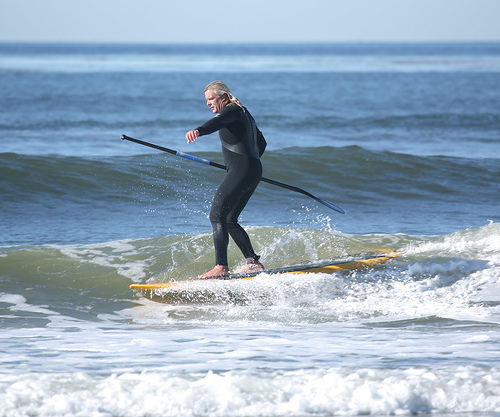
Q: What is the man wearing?
A: The man is wearing a black wetsuits.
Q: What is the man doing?
A: The man is surfing.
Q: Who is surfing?
A: A man is surfing.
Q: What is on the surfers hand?
A: The surfer is holding onto a pole.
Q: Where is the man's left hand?
A: The man's left hand is extended on the side.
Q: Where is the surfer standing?
A: The surfer is standing on a surf board.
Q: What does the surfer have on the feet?
A: The surfers feet are bare.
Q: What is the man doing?
A: Surfing.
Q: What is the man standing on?
A: Surfboard.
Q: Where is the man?
A: In the ocean.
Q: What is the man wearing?
A: Black wetsuit.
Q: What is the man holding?
A: Pole.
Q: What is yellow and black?
A: Surfboard.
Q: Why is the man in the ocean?
A: Surfing.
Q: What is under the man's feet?
A: Surfboard.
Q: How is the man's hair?
A: Long.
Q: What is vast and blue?
A: Ocean.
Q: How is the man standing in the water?
A: On a paddleboard.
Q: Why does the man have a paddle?
A: For balance and movement.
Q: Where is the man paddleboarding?
A: In the ocean.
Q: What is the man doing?
A: Surfing.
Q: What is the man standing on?
A: A surfboard.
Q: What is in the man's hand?
A: A paddle.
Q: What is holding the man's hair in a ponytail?
A: Hair tie.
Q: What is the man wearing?
A: A wet suit.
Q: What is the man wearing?
A: A wetsuit.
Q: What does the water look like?
A: Wavy.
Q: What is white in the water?
A: Foam.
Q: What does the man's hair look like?
A: Long ponytail.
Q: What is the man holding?
A: A paddle.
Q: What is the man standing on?
A: A surfboard.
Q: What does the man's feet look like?
A: Bare.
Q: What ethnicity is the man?
A: White.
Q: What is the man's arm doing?
A: Holding it out straight.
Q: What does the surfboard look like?
A: Black and yellow.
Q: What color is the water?
A: Blue.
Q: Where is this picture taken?
A: An ocean.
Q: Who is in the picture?
A: A man.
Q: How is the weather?
A: Sunny.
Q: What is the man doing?
A: Surfing.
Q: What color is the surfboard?
A: Yellow.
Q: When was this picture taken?
A: Daytime.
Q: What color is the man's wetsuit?
A: Black.